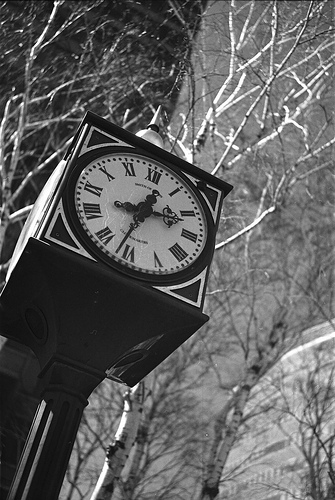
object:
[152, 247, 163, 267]
number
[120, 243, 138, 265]
roman number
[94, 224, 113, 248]
roman number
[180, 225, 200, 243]
numeral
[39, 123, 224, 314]
box face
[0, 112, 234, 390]
box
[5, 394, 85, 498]
pole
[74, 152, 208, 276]
clock face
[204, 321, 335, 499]
building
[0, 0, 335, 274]
tree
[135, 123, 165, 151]
globe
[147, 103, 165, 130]
cone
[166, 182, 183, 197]
number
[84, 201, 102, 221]
number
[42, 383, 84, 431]
shadow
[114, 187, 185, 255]
2:32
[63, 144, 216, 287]
clock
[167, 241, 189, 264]
number